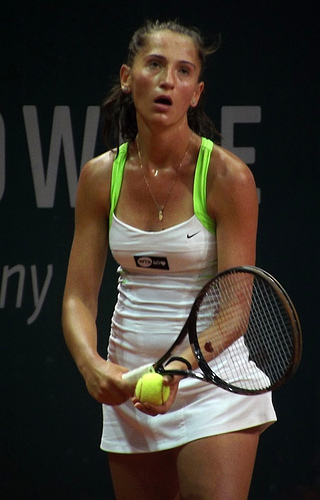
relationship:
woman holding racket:
[69, 25, 283, 499] [86, 258, 308, 414]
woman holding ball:
[69, 25, 283, 499] [132, 369, 181, 414]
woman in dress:
[69, 25, 283, 499] [93, 163, 251, 408]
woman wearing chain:
[69, 25, 283, 499] [132, 164, 184, 223]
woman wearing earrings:
[69, 25, 283, 499] [117, 87, 133, 95]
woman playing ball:
[69, 25, 283, 499] [132, 369, 170, 406]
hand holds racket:
[80, 361, 140, 411] [86, 258, 308, 414]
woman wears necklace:
[69, 25, 283, 499] [134, 149, 183, 224]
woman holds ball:
[69, 25, 283, 499] [132, 369, 181, 414]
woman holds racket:
[69, 25, 283, 499] [86, 258, 308, 414]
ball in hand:
[132, 369, 181, 414] [80, 361, 140, 411]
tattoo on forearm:
[199, 333, 223, 358] [178, 318, 265, 383]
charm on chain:
[155, 208, 171, 222] [132, 164, 184, 223]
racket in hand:
[86, 258, 308, 414] [80, 361, 140, 411]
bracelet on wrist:
[166, 353, 194, 370] [178, 346, 218, 395]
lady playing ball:
[69, 25, 283, 499] [132, 369, 170, 406]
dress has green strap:
[93, 163, 251, 408] [109, 138, 134, 207]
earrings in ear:
[117, 87, 133, 95] [113, 64, 136, 105]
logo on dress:
[132, 249, 173, 272] [93, 163, 251, 408]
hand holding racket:
[80, 361, 140, 411] [86, 258, 308, 414]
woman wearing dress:
[69, 25, 283, 499] [93, 163, 251, 408]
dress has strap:
[93, 163, 251, 408] [181, 151, 228, 209]